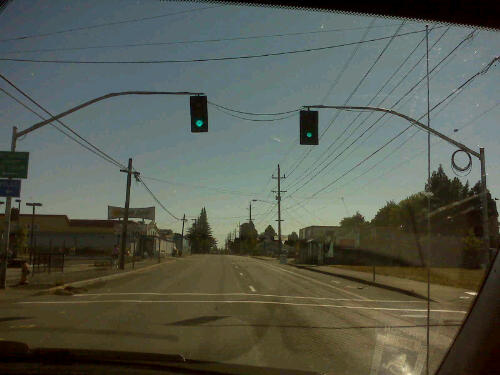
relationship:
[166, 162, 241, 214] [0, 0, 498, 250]
clouds in clear sky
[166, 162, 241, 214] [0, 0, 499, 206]
clouds in sky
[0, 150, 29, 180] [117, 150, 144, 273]
sign on metal pole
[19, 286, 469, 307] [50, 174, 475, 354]
lines on road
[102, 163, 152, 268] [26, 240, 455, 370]
pole on road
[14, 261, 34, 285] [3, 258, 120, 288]
fire hydrant on sidewalk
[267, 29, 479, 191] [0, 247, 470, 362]
wires above street